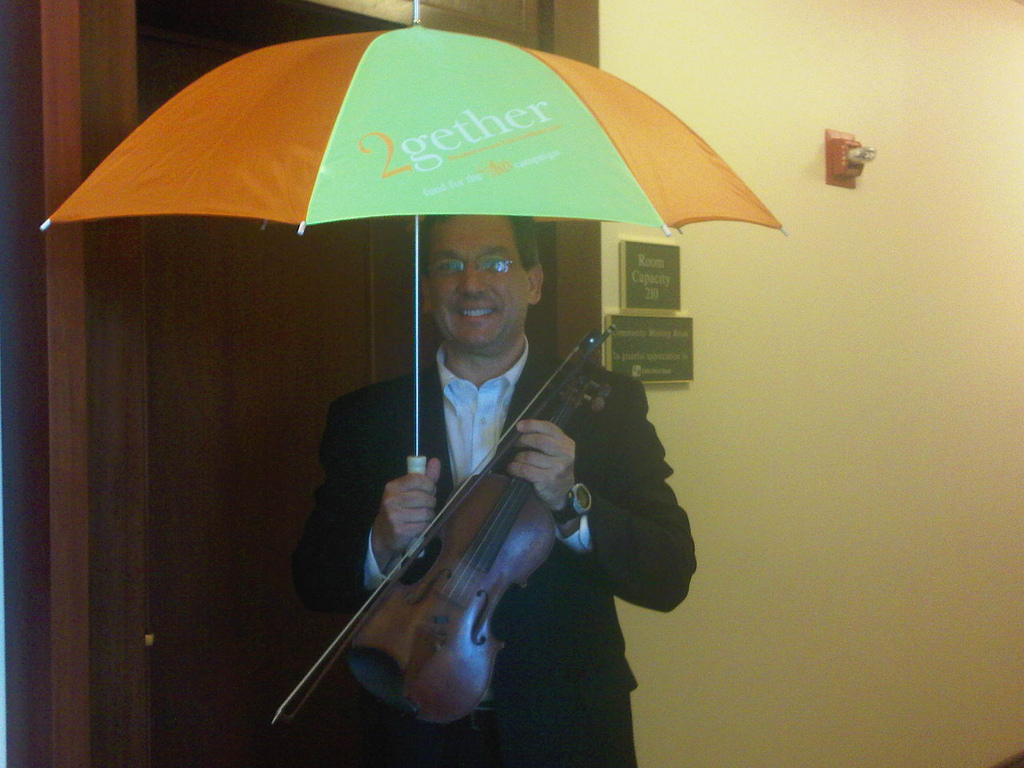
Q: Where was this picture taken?
A: In a hallway.